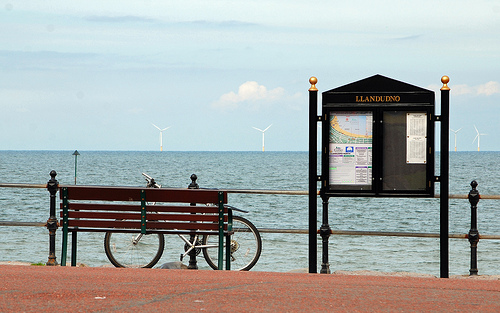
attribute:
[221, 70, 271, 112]
cloud — WISPY 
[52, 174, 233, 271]
bench — wooden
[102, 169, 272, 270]
bike — parked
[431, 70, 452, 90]
knob — GOLD 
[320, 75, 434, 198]
sign — BLACK